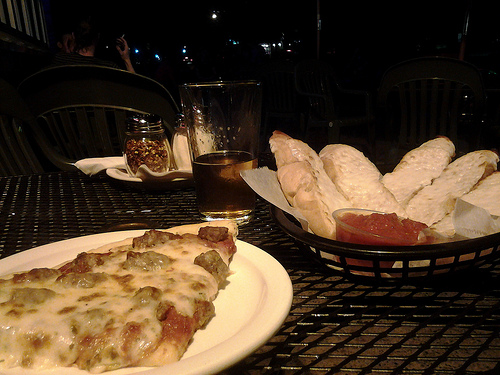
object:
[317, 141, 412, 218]
bread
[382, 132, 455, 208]
bread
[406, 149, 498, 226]
bread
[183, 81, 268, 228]
glass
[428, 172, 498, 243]
bread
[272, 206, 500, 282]
basket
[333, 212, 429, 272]
sauce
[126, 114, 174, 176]
condiments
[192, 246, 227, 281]
sausage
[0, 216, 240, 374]
pizza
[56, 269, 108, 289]
topping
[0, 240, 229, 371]
sauce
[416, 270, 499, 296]
shade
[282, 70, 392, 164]
chair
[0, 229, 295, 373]
plate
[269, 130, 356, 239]
powdered bread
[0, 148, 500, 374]
table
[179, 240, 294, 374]
edge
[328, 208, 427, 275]
cup